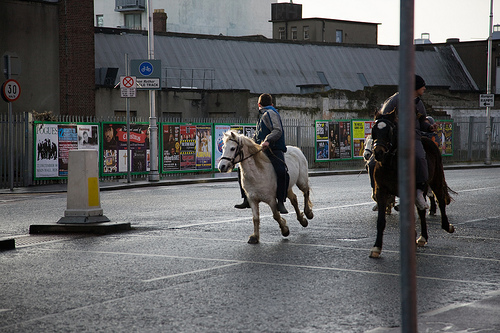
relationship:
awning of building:
[95, 25, 498, 95] [93, 22, 498, 182]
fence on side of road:
[3, 105, 492, 192] [2, 164, 497, 329]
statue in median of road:
[55, 147, 111, 222] [137, 232, 456, 287]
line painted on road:
[140, 253, 260, 296] [2, 164, 497, 329]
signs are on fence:
[159, 122, 216, 169] [163, 112, 255, 135]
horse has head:
[367, 112, 454, 258] [370, 109, 395, 161]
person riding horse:
[233, 93, 290, 213] [218, 131, 313, 244]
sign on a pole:
[114, 52, 189, 105] [383, 12, 428, 331]